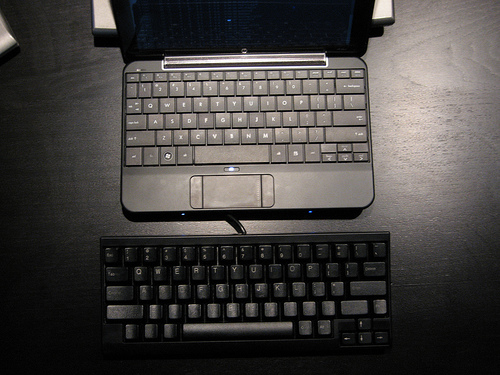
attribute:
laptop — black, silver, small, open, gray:
[107, 49, 384, 209]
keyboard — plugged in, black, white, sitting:
[155, 100, 337, 153]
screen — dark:
[161, 5, 348, 52]